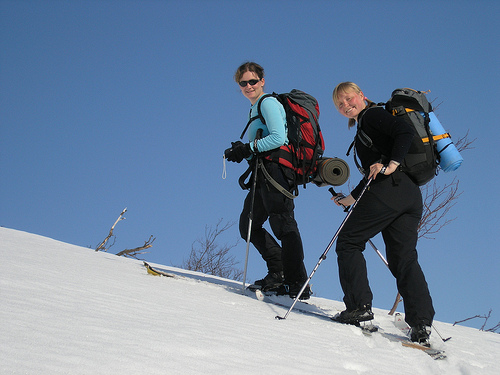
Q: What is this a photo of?
A: Skiers on a slope.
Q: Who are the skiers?
A: Two women.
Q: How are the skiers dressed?
A: They have on snow pants and fitted shirts.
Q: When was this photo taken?
A: During winter.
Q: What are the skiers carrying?
A: Backpacks.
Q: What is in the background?
A: Barren trees.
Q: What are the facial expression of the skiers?
A: They are smiling.